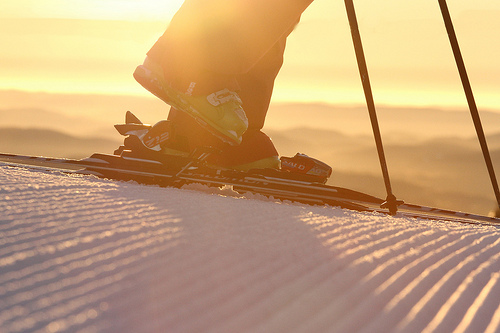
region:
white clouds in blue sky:
[38, 48, 62, 83]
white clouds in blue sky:
[308, 29, 339, 60]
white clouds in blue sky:
[374, 36, 434, 87]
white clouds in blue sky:
[37, 13, 84, 63]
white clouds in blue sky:
[35, 66, 75, 100]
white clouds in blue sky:
[14, 55, 75, 99]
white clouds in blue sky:
[26, 13, 56, 35]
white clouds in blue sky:
[28, 33, 86, 75]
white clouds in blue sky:
[82, 8, 117, 53]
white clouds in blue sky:
[299, 43, 336, 77]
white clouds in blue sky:
[373, 9, 415, 43]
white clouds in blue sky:
[379, 17, 416, 70]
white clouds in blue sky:
[35, 11, 107, 58]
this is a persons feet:
[18, 12, 483, 192]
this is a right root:
[140, 22, 284, 162]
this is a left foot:
[128, 94, 316, 179]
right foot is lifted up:
[116, 21, 311, 153]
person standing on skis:
[33, 100, 468, 242]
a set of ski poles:
[320, 11, 483, 232]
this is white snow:
[46, 151, 479, 328]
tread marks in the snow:
[43, 165, 485, 324]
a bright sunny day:
[28, 31, 480, 189]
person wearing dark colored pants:
[129, 0, 347, 125]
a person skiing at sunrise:
[2, 2, 498, 254]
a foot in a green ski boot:
[127, 50, 248, 149]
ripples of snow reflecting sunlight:
[7, 225, 496, 331]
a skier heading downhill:
[0, 14, 499, 221]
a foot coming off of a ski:
[0, 37, 497, 226]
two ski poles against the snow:
[332, 0, 498, 228]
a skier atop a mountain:
[40, 0, 497, 233]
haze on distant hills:
[2, 82, 374, 169]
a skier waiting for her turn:
[5, 4, 497, 236]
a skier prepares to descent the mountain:
[22, 6, 496, 241]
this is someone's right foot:
[112, 43, 262, 143]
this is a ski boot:
[123, 46, 266, 147]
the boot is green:
[130, 45, 257, 156]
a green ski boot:
[125, 39, 267, 153]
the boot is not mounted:
[108, 39, 268, 147]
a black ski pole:
[337, 0, 438, 242]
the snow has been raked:
[7, 171, 498, 330]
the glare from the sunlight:
[100, 3, 305, 145]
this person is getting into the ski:
[113, 3, 315, 190]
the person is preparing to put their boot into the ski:
[126, 3, 316, 198]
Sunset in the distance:
[23, 7, 117, 69]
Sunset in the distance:
[10, 3, 120, 82]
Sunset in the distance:
[14, 8, 114, 43]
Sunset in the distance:
[41, 8, 113, 70]